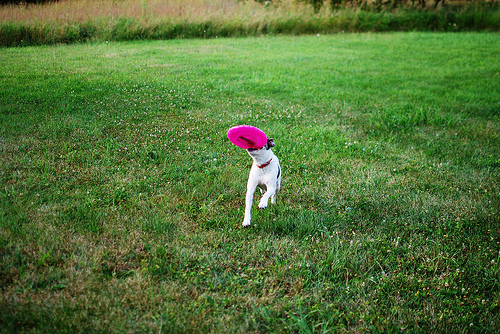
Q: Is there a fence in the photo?
A: No, there are no fences.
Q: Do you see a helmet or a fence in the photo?
A: No, there are no fences or helmets.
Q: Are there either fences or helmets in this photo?
A: No, there are no fences or helmets.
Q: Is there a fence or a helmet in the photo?
A: No, there are no fences or helmets.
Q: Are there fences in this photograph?
A: No, there are no fences.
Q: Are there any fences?
A: No, there are no fences.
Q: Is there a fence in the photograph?
A: No, there are no fences.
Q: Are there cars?
A: No, there are no cars.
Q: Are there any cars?
A: No, there are no cars.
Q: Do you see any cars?
A: No, there are no cars.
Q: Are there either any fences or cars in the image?
A: No, there are no cars or fences.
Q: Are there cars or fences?
A: No, there are no cars or fences.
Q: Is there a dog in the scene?
A: Yes, there is a dog.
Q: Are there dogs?
A: Yes, there is a dog.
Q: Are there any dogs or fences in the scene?
A: Yes, there is a dog.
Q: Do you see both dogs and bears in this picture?
A: No, there is a dog but no bears.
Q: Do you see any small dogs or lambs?
A: Yes, there is a small dog.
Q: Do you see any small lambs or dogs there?
A: Yes, there is a small dog.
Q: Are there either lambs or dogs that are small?
A: Yes, the dog is small.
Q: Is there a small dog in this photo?
A: Yes, there is a small dog.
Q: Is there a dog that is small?
A: Yes, there is a dog that is small.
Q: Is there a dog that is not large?
A: Yes, there is a small dog.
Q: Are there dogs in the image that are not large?
A: Yes, there is a small dog.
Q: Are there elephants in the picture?
A: No, there are no elephants.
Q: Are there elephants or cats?
A: No, there are no elephants or cats.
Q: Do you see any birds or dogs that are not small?
A: No, there is a dog but it is small.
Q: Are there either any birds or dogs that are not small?
A: No, there is a dog but it is small.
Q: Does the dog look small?
A: Yes, the dog is small.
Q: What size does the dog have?
A: The dog has small size.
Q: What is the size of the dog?
A: The dog is small.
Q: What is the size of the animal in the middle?
A: The dog is small.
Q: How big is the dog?
A: The dog is small.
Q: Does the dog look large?
A: No, the dog is small.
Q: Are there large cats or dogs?
A: No, there is a dog but it is small.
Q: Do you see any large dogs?
A: No, there is a dog but it is small.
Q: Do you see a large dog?
A: No, there is a dog but it is small.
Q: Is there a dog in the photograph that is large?
A: No, there is a dog but it is small.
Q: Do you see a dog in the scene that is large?
A: No, there is a dog but it is small.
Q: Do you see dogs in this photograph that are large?
A: No, there is a dog but it is small.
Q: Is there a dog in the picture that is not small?
A: No, there is a dog but it is small.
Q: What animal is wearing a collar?
A: The dog is wearing a collar.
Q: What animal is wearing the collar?
A: The dog is wearing a collar.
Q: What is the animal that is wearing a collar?
A: The animal is a dog.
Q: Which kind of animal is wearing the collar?
A: The animal is a dog.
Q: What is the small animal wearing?
A: The dog is wearing a collar.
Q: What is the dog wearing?
A: The dog is wearing a collar.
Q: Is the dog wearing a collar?
A: Yes, the dog is wearing a collar.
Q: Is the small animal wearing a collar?
A: Yes, the dog is wearing a collar.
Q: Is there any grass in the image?
A: Yes, there is grass.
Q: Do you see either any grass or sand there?
A: Yes, there is grass.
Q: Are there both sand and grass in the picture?
A: No, there is grass but no sand.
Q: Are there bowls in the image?
A: No, there are no bowls.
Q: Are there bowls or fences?
A: No, there are no bowls or fences.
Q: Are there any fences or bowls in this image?
A: No, there are no bowls or fences.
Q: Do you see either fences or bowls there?
A: No, there are no bowls or fences.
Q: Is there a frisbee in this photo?
A: Yes, there is a frisbee.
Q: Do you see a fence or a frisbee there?
A: Yes, there is a frisbee.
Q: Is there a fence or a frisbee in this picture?
A: Yes, there is a frisbee.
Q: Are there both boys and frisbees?
A: No, there is a frisbee but no boys.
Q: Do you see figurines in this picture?
A: No, there are no figurines.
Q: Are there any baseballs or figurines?
A: No, there are no figurines or baseballs.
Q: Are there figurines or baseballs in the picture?
A: No, there are no figurines or baseballs.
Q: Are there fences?
A: No, there are no fences.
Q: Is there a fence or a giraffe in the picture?
A: No, there are no fences or giraffes.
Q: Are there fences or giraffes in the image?
A: No, there are no fences or giraffes.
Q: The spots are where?
A: The spots are in the field.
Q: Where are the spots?
A: The spots are in the field.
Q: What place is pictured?
A: It is a lawn.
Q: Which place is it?
A: It is a lawn.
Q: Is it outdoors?
A: Yes, it is outdoors.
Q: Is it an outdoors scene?
A: Yes, it is outdoors.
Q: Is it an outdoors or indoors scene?
A: It is outdoors.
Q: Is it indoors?
A: No, it is outdoors.